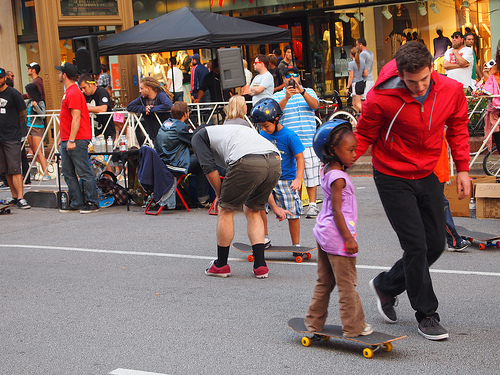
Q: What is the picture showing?
A: It is showing a street.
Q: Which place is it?
A: It is a street.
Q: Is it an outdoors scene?
A: Yes, it is outdoors.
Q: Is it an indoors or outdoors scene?
A: It is outdoors.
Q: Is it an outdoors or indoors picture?
A: It is outdoors.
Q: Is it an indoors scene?
A: No, it is outdoors.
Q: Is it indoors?
A: No, it is outdoors.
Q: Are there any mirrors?
A: No, there are no mirrors.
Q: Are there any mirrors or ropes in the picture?
A: No, there are no mirrors or ropes.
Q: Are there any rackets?
A: No, there are no rackets.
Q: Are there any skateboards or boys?
A: Yes, there is a skateboard.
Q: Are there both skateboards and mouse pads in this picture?
A: No, there is a skateboard but no mouse pads.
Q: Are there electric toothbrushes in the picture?
A: No, there are no electric toothbrushes.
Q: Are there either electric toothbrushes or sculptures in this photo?
A: No, there are no electric toothbrushes or sculptures.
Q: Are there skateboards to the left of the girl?
A: Yes, there is a skateboard to the left of the girl.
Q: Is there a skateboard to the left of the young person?
A: Yes, there is a skateboard to the left of the girl.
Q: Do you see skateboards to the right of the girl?
A: No, the skateboard is to the left of the girl.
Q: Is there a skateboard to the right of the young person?
A: No, the skateboard is to the left of the girl.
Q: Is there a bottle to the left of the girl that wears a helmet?
A: No, there is a skateboard to the left of the girl.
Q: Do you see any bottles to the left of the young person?
A: No, there is a skateboard to the left of the girl.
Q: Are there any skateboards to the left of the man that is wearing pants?
A: Yes, there is a skateboard to the left of the man.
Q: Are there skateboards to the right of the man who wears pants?
A: No, the skateboard is to the left of the man.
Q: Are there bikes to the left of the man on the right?
A: No, there is a skateboard to the left of the man.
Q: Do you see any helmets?
A: Yes, there is a helmet.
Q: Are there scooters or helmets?
A: Yes, there is a helmet.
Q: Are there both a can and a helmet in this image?
A: No, there is a helmet but no cans.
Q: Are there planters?
A: No, there are no planters.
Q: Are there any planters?
A: No, there are no planters.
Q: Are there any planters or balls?
A: No, there are no planters or balls.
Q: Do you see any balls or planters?
A: No, there are no planters or balls.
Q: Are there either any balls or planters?
A: No, there are no planters or balls.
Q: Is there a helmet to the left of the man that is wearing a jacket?
A: Yes, there is a helmet to the left of the man.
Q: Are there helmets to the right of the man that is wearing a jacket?
A: No, the helmet is to the left of the man.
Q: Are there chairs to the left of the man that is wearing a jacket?
A: No, there is a helmet to the left of the man.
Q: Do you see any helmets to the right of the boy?
A: Yes, there is a helmet to the right of the boy.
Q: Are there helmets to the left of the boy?
A: No, the helmet is to the right of the boy.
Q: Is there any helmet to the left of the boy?
A: No, the helmet is to the right of the boy.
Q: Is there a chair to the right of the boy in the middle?
A: No, there is a helmet to the right of the boy.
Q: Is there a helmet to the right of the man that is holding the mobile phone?
A: Yes, there is a helmet to the right of the man.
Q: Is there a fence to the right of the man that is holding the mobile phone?
A: No, there is a helmet to the right of the man.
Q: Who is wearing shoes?
A: The man is wearing shoes.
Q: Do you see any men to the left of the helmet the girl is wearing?
A: Yes, there is a man to the left of the helmet.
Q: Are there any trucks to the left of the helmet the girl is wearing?
A: No, there is a man to the left of the helmet.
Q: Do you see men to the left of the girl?
A: Yes, there is a man to the left of the girl.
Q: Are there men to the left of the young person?
A: Yes, there is a man to the left of the girl.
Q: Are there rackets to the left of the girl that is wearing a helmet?
A: No, there is a man to the left of the girl.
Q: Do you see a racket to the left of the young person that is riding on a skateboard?
A: No, there is a man to the left of the girl.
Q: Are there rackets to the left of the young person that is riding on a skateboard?
A: No, there is a man to the left of the girl.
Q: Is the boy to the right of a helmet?
A: No, the boy is to the left of a helmet.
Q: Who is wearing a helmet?
A: The boy is wearing a helmet.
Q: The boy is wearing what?
A: The boy is wearing a helmet.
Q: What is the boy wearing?
A: The boy is wearing a helmet.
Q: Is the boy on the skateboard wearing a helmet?
A: Yes, the boy is wearing a helmet.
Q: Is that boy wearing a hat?
A: No, the boy is wearing a helmet.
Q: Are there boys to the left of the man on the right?
A: Yes, there is a boy to the left of the man.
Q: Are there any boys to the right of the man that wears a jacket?
A: No, the boy is to the left of the man.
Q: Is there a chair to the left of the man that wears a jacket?
A: No, there is a boy to the left of the man.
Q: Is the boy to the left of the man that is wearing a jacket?
A: Yes, the boy is to the left of the man.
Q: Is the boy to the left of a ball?
A: No, the boy is to the left of the man.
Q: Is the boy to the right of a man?
A: No, the boy is to the left of a man.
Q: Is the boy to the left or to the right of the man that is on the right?
A: The boy is to the left of the man.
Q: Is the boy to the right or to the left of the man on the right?
A: The boy is to the left of the man.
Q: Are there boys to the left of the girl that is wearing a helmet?
A: Yes, there is a boy to the left of the girl.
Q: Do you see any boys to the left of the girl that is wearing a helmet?
A: Yes, there is a boy to the left of the girl.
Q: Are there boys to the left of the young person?
A: Yes, there is a boy to the left of the girl.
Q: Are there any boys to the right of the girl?
A: No, the boy is to the left of the girl.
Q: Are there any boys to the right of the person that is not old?
A: No, the boy is to the left of the girl.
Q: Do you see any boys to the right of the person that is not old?
A: No, the boy is to the left of the girl.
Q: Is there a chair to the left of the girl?
A: No, there is a boy to the left of the girl.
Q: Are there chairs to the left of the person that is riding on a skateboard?
A: No, there is a boy to the left of the girl.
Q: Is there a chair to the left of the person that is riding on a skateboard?
A: No, there is a boy to the left of the girl.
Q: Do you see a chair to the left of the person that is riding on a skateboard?
A: No, there is a boy to the left of the girl.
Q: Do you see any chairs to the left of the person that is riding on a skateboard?
A: No, there is a boy to the left of the girl.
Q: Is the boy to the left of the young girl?
A: Yes, the boy is to the left of the girl.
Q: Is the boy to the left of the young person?
A: Yes, the boy is to the left of the girl.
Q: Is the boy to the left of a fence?
A: No, the boy is to the left of the girl.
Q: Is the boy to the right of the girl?
A: No, the boy is to the left of the girl.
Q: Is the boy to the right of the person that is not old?
A: No, the boy is to the left of the girl.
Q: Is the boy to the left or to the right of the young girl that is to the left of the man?
A: The boy is to the left of the girl.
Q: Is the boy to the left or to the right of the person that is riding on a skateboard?
A: The boy is to the left of the girl.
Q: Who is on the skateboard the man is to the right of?
A: The boy is on the skateboard.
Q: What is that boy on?
A: The boy is on the skateboard.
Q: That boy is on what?
A: The boy is on the skateboard.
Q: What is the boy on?
A: The boy is on the skateboard.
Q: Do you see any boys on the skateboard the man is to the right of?
A: Yes, there is a boy on the skateboard.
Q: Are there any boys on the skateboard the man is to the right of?
A: Yes, there is a boy on the skateboard.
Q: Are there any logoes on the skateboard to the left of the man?
A: No, there is a boy on the skateboard.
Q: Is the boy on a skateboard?
A: Yes, the boy is on a skateboard.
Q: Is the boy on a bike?
A: No, the boy is on a skateboard.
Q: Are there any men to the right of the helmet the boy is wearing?
A: Yes, there is a man to the right of the helmet.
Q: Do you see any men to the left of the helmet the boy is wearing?
A: No, the man is to the right of the helmet.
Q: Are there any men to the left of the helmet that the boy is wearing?
A: No, the man is to the right of the helmet.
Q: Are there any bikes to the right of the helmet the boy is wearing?
A: No, there is a man to the right of the helmet.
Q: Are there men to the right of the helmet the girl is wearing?
A: Yes, there is a man to the right of the helmet.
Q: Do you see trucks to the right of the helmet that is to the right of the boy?
A: No, there is a man to the right of the helmet.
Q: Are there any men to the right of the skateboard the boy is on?
A: Yes, there is a man to the right of the skateboard.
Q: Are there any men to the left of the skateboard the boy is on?
A: No, the man is to the right of the skateboard.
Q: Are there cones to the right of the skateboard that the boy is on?
A: No, there is a man to the right of the skateboard.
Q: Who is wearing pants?
A: The man is wearing pants.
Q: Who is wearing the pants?
A: The man is wearing pants.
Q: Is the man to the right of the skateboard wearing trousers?
A: Yes, the man is wearing trousers.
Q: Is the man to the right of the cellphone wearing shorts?
A: No, the man is wearing trousers.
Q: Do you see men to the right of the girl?
A: Yes, there is a man to the right of the girl.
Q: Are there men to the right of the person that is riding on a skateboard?
A: Yes, there is a man to the right of the girl.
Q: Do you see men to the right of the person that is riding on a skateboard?
A: Yes, there is a man to the right of the girl.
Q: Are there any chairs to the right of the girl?
A: No, there is a man to the right of the girl.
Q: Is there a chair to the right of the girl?
A: No, there is a man to the right of the girl.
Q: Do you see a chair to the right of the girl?
A: No, there is a man to the right of the girl.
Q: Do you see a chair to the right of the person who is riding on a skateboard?
A: No, there is a man to the right of the girl.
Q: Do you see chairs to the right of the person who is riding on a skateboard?
A: No, there is a man to the right of the girl.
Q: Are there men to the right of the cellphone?
A: Yes, there is a man to the right of the cellphone.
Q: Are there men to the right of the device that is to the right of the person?
A: Yes, there is a man to the right of the cellphone.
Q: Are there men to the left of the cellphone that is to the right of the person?
A: No, the man is to the right of the cell phone.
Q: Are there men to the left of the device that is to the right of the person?
A: No, the man is to the right of the cell phone.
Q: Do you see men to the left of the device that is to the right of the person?
A: No, the man is to the right of the cell phone.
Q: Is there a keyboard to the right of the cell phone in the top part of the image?
A: No, there is a man to the right of the cellphone.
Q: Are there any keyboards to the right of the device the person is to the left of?
A: No, there is a man to the right of the cellphone.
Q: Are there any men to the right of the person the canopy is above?
A: Yes, there is a man to the right of the person.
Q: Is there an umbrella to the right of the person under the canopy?
A: No, there is a man to the right of the person.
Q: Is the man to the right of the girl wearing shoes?
A: Yes, the man is wearing shoes.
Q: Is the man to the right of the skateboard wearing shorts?
A: No, the man is wearing shoes.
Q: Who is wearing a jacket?
A: The man is wearing a jacket.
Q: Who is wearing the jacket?
A: The man is wearing a jacket.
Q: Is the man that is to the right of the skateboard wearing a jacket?
A: Yes, the man is wearing a jacket.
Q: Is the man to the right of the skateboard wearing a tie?
A: No, the man is wearing a jacket.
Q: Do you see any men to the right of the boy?
A: Yes, there is a man to the right of the boy.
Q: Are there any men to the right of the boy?
A: Yes, there is a man to the right of the boy.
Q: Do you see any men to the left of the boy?
A: No, the man is to the right of the boy.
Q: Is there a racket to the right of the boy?
A: No, there is a man to the right of the boy.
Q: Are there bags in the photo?
A: No, there are no bags.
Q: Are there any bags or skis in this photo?
A: No, there are no bags or skis.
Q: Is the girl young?
A: Yes, the girl is young.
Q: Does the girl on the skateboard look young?
A: Yes, the girl is young.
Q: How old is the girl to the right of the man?
A: The girl is young.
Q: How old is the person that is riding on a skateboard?
A: The girl is young.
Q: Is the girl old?
A: No, the girl is young.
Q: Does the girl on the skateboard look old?
A: No, the girl is young.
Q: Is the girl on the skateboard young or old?
A: The girl is young.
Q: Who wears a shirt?
A: The girl wears a shirt.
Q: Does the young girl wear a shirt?
A: Yes, the girl wears a shirt.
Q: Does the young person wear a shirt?
A: Yes, the girl wears a shirt.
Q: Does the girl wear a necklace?
A: No, the girl wears a shirt.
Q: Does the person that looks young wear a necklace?
A: No, the girl wears a shirt.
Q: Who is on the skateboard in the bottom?
A: The girl is on the skateboard.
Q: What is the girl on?
A: The girl is on the skateboard.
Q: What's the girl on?
A: The girl is on the skateboard.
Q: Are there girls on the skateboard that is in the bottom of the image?
A: Yes, there is a girl on the skateboard.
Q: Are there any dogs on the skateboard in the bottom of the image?
A: No, there is a girl on the skateboard.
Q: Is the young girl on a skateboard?
A: Yes, the girl is on a skateboard.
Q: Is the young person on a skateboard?
A: Yes, the girl is on a skateboard.